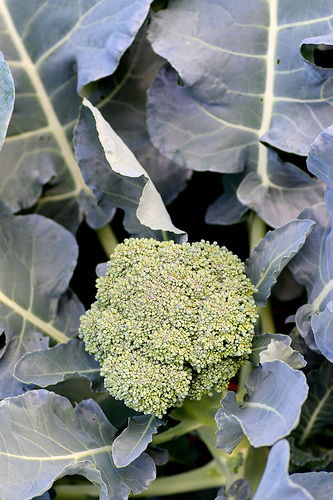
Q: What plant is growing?
A: Broccoli.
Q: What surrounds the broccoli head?
A: Leaves.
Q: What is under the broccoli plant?
A: Dirt.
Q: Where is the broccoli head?
A: Center of the plant.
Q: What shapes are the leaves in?
A: Curly.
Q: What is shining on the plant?
A: Sunlight.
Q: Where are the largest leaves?
A: Top of the image.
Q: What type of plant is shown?
A: Broccoli.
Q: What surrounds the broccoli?
A: Leaves.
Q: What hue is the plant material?
A: Green.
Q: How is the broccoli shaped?
A: In a ball.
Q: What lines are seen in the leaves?
A: Stems.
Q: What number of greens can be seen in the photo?
A: Three.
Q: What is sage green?
A: The leaves.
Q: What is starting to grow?
A: Broccoli.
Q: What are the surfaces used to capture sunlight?
A: Leaves.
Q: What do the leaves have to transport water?
A: Veins.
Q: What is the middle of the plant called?
A: Head.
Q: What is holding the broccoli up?
A: Stem.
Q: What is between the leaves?
A: Dark spaces.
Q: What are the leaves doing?
A: Starting to curl.